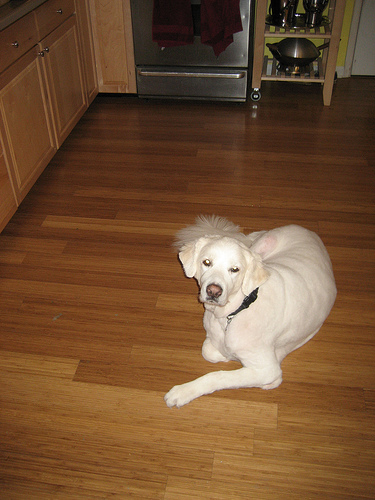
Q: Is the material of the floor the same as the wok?
A: No, the floor is made of wood and the wok is made of metal.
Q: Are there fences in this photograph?
A: No, there are no fences.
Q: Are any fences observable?
A: No, there are no fences.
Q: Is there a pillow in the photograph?
A: No, there are no pillows.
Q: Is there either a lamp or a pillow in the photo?
A: No, there are no pillows or lamps.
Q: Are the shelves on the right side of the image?
A: Yes, the shelves are on the right of the image.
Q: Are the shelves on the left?
A: No, the shelves are on the right of the image.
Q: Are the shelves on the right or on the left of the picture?
A: The shelves are on the right of the image.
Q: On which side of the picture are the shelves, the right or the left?
A: The shelves are on the right of the image.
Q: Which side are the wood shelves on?
A: The shelves are on the right of the image.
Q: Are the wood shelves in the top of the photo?
A: Yes, the shelves are in the top of the image.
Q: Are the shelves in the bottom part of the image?
A: No, the shelves are in the top of the image.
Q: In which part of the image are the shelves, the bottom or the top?
A: The shelves are in the top of the image.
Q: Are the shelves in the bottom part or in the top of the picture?
A: The shelves are in the top of the image.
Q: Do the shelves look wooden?
A: Yes, the shelves are wooden.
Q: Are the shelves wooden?
A: Yes, the shelves are wooden.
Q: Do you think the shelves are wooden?
A: Yes, the shelves are wooden.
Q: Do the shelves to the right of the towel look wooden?
A: Yes, the shelves are wooden.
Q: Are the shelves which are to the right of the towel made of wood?
A: Yes, the shelves are made of wood.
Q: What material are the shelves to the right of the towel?
A: The shelves are made of wood.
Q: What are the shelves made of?
A: The shelves are made of wood.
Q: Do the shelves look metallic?
A: No, the shelves are wooden.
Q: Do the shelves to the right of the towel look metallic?
A: No, the shelves are wooden.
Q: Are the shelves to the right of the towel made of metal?
A: No, the shelves are made of wood.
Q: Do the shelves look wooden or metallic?
A: The shelves are wooden.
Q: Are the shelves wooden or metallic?
A: The shelves are wooden.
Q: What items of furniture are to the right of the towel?
A: The pieces of furniture are shelves.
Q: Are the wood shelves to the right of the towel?
A: Yes, the shelves are to the right of the towel.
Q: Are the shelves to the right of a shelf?
A: No, the shelves are to the right of the towel.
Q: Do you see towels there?
A: Yes, there is a towel.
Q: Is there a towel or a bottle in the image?
A: Yes, there is a towel.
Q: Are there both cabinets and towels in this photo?
A: Yes, there are both a towel and a cabinet.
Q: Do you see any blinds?
A: No, there are no blinds.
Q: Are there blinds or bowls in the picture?
A: No, there are no blinds or bowls.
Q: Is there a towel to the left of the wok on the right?
A: Yes, there is a towel to the left of the wok.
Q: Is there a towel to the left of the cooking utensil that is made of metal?
A: Yes, there is a towel to the left of the wok.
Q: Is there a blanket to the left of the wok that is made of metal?
A: No, there is a towel to the left of the wok.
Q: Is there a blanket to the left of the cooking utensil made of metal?
A: No, there is a towel to the left of the wok.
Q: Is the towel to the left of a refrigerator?
A: No, the towel is to the left of the wok.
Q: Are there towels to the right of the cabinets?
A: Yes, there is a towel to the right of the cabinets.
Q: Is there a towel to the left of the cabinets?
A: No, the towel is to the right of the cabinets.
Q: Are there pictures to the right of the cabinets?
A: No, there is a towel to the right of the cabinets.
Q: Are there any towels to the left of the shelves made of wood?
A: Yes, there is a towel to the left of the shelves.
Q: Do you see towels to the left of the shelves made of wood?
A: Yes, there is a towel to the left of the shelves.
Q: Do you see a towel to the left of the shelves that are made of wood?
A: Yes, there is a towel to the left of the shelves.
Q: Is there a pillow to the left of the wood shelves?
A: No, there is a towel to the left of the shelves.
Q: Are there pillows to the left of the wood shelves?
A: No, there is a towel to the left of the shelves.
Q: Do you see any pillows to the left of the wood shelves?
A: No, there is a towel to the left of the shelves.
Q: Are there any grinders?
A: No, there are no grinders.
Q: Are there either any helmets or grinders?
A: No, there are no grinders or helmets.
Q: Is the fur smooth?
A: Yes, the fur is smooth.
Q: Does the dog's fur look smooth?
A: Yes, the fur is smooth.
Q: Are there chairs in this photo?
A: No, there are no chairs.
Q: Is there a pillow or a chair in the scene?
A: No, there are no chairs or pillows.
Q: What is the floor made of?
A: The floor is made of wood.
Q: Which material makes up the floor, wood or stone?
A: The floor is made of wood.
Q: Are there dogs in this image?
A: Yes, there is a dog.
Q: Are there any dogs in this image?
A: Yes, there is a dog.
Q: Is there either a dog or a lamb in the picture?
A: Yes, there is a dog.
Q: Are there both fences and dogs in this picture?
A: No, there is a dog but no fences.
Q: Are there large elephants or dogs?
A: Yes, there is a large dog.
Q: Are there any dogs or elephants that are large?
A: Yes, the dog is large.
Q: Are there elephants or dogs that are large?
A: Yes, the dog is large.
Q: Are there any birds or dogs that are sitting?
A: Yes, the dog is sitting.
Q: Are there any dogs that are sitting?
A: Yes, there is a dog that is sitting.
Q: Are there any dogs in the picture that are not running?
A: Yes, there is a dog that is sitting.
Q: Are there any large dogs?
A: Yes, there is a large dog.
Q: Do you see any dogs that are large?
A: Yes, there is a dog that is large.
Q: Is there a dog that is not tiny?
A: Yes, there is a large dog.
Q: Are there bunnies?
A: No, there are no bunnies.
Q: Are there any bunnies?
A: No, there are no bunnies.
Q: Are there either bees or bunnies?
A: No, there are no bunnies or bees.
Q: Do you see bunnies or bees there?
A: No, there are no bunnies or bees.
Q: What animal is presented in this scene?
A: The animal is a dog.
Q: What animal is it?
A: The animal is a dog.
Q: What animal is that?
A: This is a dog.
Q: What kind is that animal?
A: This is a dog.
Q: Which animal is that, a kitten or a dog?
A: This is a dog.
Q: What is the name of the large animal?
A: The animal is a dog.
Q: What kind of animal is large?
A: The animal is a dog.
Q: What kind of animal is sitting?
A: The animal is a dog.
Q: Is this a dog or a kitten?
A: This is a dog.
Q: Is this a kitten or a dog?
A: This is a dog.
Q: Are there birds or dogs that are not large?
A: No, there is a dog but it is large.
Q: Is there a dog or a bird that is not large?
A: No, there is a dog but it is large.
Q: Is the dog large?
A: Yes, the dog is large.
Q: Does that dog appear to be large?
A: Yes, the dog is large.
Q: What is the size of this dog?
A: The dog is large.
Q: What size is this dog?
A: The dog is large.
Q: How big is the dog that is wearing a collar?
A: The dog is large.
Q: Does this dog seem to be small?
A: No, the dog is large.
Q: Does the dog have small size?
A: No, the dog is large.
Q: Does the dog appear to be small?
A: No, the dog is large.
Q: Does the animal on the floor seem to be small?
A: No, the dog is large.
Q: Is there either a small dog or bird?
A: No, there is a dog but it is large.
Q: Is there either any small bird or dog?
A: No, there is a dog but it is large.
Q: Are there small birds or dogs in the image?
A: No, there is a dog but it is large.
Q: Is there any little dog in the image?
A: No, there is a dog but it is large.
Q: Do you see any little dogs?
A: No, there is a dog but it is large.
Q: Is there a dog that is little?
A: No, there is a dog but it is large.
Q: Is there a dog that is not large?
A: No, there is a dog but it is large.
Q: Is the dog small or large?
A: The dog is large.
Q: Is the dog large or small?
A: The dog is large.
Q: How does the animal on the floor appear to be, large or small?
A: The dog is large.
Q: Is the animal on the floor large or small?
A: The dog is large.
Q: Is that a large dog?
A: Yes, that is a large dog.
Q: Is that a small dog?
A: No, that is a large dog.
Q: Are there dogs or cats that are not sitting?
A: No, there is a dog but it is sitting.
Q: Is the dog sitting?
A: Yes, the dog is sitting.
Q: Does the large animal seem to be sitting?
A: Yes, the dog is sitting.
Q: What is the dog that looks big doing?
A: The dog is sitting.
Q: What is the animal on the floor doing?
A: The dog is sitting.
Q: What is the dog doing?
A: The dog is sitting.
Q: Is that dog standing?
A: No, the dog is sitting.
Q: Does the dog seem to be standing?
A: No, the dog is sitting.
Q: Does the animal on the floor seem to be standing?
A: No, the dog is sitting.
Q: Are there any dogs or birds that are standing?
A: No, there is a dog but it is sitting.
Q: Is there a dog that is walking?
A: No, there is a dog but it is sitting.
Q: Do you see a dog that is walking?
A: No, there is a dog but it is sitting.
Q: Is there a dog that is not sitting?
A: No, there is a dog but it is sitting.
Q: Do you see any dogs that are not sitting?
A: No, there is a dog but it is sitting.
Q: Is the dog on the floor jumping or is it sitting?
A: The dog is sitting.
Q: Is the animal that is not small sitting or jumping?
A: The dog is sitting.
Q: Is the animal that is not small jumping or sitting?
A: The dog is sitting.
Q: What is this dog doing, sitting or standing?
A: The dog is sitting.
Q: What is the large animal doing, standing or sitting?
A: The dog is sitting.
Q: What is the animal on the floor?
A: The animal is a dog.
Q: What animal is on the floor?
A: The animal is a dog.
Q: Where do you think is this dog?
A: The dog is on the floor.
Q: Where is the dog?
A: The dog is on the floor.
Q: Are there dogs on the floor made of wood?
A: Yes, there is a dog on the floor.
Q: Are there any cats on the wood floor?
A: No, there is a dog on the floor.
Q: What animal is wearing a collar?
A: The animal is a dog.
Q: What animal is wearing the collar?
A: The animal is a dog.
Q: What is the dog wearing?
A: The dog is wearing a collar.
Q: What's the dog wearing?
A: The dog is wearing a collar.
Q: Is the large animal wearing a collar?
A: Yes, the dog is wearing a collar.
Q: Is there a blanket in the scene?
A: No, there are no blankets.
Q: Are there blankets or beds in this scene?
A: No, there are no blankets or beds.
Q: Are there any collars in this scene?
A: Yes, there is a collar.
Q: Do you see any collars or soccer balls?
A: Yes, there is a collar.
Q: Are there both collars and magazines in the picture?
A: No, there is a collar but no magazines.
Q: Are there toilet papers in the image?
A: No, there are no toilet papers.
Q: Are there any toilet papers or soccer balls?
A: No, there are no toilet papers or soccer balls.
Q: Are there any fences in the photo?
A: No, there are no fences.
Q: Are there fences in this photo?
A: No, there are no fences.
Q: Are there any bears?
A: No, there are no bears.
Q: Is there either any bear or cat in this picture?
A: No, there are no bears or cats.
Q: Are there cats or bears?
A: No, there are no bears or cats.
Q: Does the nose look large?
A: Yes, the nose is large.